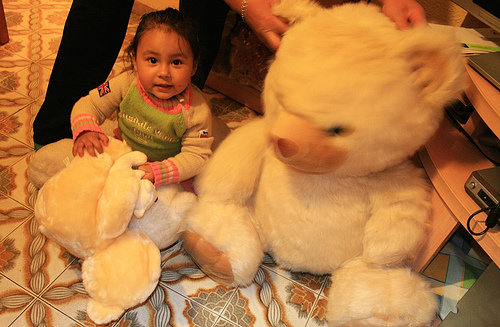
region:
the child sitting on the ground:
[70, 10, 211, 210]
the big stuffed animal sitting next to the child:
[195, 0, 462, 325]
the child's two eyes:
[140, 52, 185, 64]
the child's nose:
[152, 60, 168, 75]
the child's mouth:
[150, 80, 175, 90]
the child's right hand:
[67, 120, 107, 155]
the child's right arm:
[65, 66, 130, 156]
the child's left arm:
[134, 95, 213, 185]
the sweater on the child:
[67, 70, 217, 184]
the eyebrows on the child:
[137, 46, 192, 60]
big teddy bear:
[229, 18, 467, 326]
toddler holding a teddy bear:
[38, 92, 173, 325]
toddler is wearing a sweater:
[87, 27, 211, 194]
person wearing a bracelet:
[222, 3, 278, 23]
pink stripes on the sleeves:
[137, 155, 199, 199]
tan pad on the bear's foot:
[179, 226, 276, 282]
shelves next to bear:
[390, 54, 499, 307]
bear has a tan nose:
[275, 130, 314, 171]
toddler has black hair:
[97, 6, 234, 66]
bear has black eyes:
[326, 80, 362, 157]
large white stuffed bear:
[212, 5, 447, 323]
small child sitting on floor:
[27, 12, 233, 315]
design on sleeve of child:
[92, 69, 121, 99]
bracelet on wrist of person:
[233, 0, 253, 25]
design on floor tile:
[173, 278, 299, 325]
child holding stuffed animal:
[17, 5, 209, 325]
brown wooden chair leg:
[0, 0, 16, 61]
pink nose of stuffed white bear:
[268, 131, 311, 168]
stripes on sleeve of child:
[145, 155, 185, 185]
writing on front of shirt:
[112, 107, 189, 154]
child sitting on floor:
[72, 12, 226, 219]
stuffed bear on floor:
[204, 32, 441, 316]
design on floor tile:
[14, 248, 53, 313]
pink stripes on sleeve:
[146, 157, 181, 189]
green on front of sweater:
[112, 98, 193, 147]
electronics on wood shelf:
[457, 169, 494, 228]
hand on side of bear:
[244, 2, 301, 50]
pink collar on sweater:
[132, 82, 199, 117]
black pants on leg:
[45, 7, 135, 90]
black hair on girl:
[149, 8, 212, 55]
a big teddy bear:
[192, 5, 447, 315]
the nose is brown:
[257, 131, 311, 166]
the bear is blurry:
[227, 1, 439, 304]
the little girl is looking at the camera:
[77, 5, 210, 165]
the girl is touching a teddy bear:
[40, 86, 166, 209]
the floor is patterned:
[130, 255, 292, 319]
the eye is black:
[326, 113, 366, 149]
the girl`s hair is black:
[120, 0, 208, 66]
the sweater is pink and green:
[72, 68, 209, 183]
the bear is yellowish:
[30, 134, 177, 311]